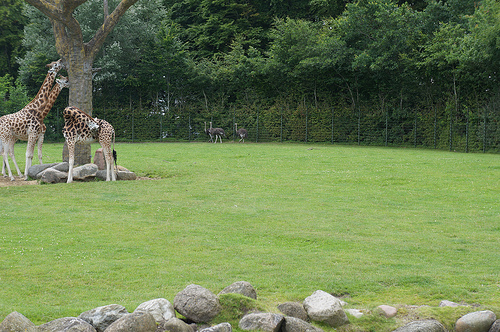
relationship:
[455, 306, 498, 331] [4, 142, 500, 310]
stone by grass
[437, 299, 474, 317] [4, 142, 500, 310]
stone by grass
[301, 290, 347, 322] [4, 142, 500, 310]
stone by grass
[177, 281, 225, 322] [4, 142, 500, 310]
stone by grass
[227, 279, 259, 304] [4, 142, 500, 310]
stone by grass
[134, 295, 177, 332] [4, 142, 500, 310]
stone by grass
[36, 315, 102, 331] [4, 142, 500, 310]
stone by grass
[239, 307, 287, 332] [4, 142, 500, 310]
stone by grass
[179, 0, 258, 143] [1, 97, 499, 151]
tree outside fence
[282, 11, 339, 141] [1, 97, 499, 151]
tree outside fence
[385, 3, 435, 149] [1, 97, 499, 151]
tree outside fence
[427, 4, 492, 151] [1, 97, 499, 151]
tree outside fence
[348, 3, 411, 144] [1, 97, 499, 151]
tree outside fence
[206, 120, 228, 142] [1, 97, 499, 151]
ostrich near fence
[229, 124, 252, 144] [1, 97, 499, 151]
ostrich near fence